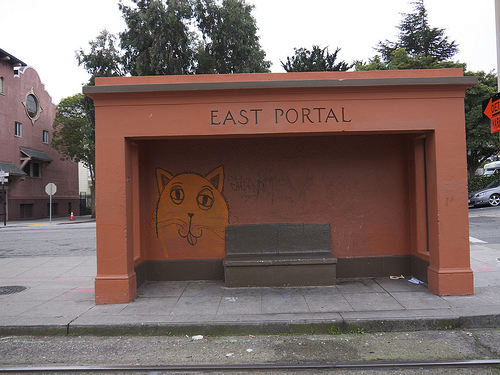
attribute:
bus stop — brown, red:
[88, 69, 486, 304]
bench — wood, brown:
[222, 220, 339, 286]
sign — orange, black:
[475, 88, 499, 135]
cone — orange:
[67, 207, 78, 224]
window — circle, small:
[22, 85, 44, 123]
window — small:
[12, 117, 26, 140]